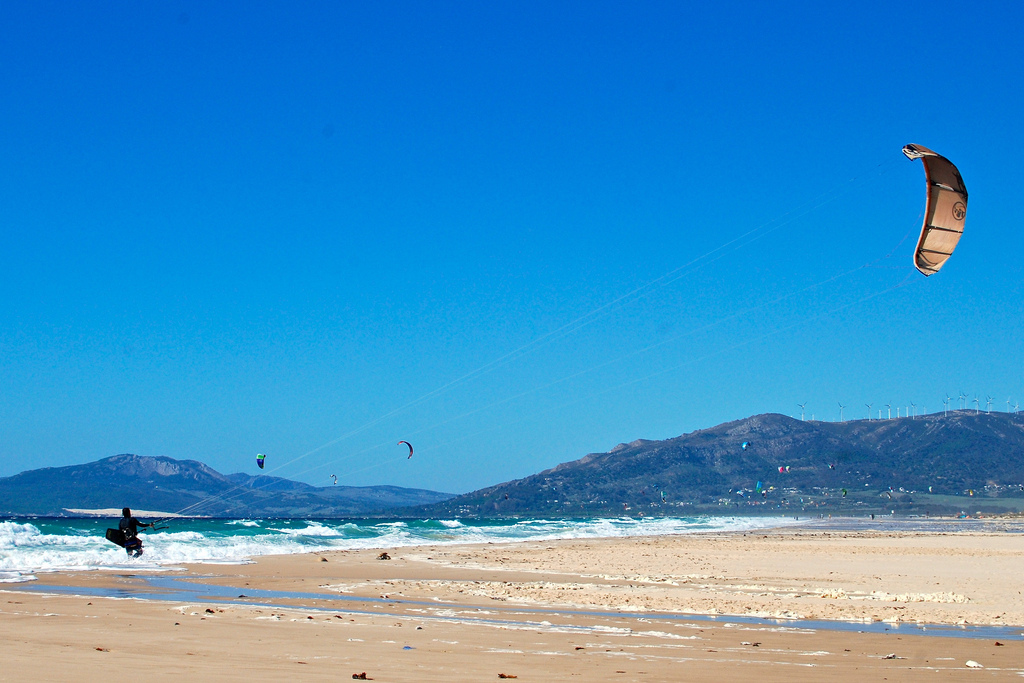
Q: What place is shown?
A: It is a beach.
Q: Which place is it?
A: It is a beach.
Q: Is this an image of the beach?
A: Yes, it is showing the beach.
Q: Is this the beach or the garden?
A: It is the beach.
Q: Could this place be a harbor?
A: No, it is a beach.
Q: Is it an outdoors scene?
A: Yes, it is outdoors.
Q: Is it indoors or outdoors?
A: It is outdoors.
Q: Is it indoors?
A: No, it is outdoors.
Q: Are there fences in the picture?
A: No, there are no fences.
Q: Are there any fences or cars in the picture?
A: No, there are no fences or cars.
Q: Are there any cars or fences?
A: No, there are no fences or cars.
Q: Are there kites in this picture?
A: Yes, there is a kite.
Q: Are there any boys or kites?
A: Yes, there is a kite.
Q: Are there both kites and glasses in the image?
A: No, there is a kite but no glasses.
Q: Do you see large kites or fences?
A: Yes, there is a large kite.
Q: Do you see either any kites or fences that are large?
A: Yes, the kite is large.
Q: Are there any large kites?
A: Yes, there is a large kite.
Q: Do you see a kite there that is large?
A: Yes, there is a kite that is large.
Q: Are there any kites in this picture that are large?
A: Yes, there is a kite that is large.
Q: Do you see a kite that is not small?
A: Yes, there is a large kite.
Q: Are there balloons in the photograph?
A: No, there are no balloons.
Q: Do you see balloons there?
A: No, there are no balloons.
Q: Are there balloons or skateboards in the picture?
A: No, there are no balloons or skateboards.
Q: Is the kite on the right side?
A: Yes, the kite is on the right of the image.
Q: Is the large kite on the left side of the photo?
A: No, the kite is on the right of the image.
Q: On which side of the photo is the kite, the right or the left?
A: The kite is on the right of the image.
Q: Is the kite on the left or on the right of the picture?
A: The kite is on the right of the image.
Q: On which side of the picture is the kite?
A: The kite is on the right of the image.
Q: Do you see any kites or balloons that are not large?
A: No, there is a kite but it is large.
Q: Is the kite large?
A: Yes, the kite is large.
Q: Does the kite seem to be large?
A: Yes, the kite is large.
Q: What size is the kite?
A: The kite is large.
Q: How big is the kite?
A: The kite is large.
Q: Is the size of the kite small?
A: No, the kite is large.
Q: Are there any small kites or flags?
A: No, there is a kite but it is large.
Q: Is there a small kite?
A: No, there is a kite but it is large.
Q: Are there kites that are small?
A: No, there is a kite but it is large.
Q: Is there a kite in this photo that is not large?
A: No, there is a kite but it is large.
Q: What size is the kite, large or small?
A: The kite is large.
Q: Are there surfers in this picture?
A: Yes, there is a surfer.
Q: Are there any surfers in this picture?
A: Yes, there is a surfer.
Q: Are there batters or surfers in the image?
A: Yes, there is a surfer.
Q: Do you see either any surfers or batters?
A: Yes, there is a surfer.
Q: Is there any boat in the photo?
A: No, there are no boats.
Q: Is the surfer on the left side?
A: Yes, the surfer is on the left of the image.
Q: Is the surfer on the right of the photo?
A: No, the surfer is on the left of the image.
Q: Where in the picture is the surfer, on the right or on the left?
A: The surfer is on the left of the image.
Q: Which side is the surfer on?
A: The surfer is on the left of the image.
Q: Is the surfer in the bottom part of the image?
A: Yes, the surfer is in the bottom of the image.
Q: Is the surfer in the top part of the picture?
A: No, the surfer is in the bottom of the image.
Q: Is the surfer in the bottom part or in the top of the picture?
A: The surfer is in the bottom of the image.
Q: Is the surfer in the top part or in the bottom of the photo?
A: The surfer is in the bottom of the image.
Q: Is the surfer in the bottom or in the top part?
A: The surfer is in the bottom of the image.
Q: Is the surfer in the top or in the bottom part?
A: The surfer is in the bottom of the image.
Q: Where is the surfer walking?
A: The surfer is walking in the ocean.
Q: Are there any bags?
A: No, there are no bags.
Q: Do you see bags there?
A: No, there are no bags.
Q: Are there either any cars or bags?
A: No, there are no bags or cars.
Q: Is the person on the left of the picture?
A: Yes, the person is on the left of the image.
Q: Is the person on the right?
A: No, the person is on the left of the image.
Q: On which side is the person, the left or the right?
A: The person is on the left of the image.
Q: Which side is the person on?
A: The person is on the left of the image.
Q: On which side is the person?
A: The person is on the left of the image.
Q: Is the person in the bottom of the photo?
A: Yes, the person is in the bottom of the image.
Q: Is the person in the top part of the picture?
A: No, the person is in the bottom of the image.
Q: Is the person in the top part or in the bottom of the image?
A: The person is in the bottom of the image.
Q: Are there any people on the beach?
A: Yes, there is a person on the beach.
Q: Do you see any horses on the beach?
A: No, there is a person on the beach.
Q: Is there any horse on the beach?
A: No, there is a person on the beach.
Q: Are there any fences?
A: No, there are no fences.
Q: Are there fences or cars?
A: No, there are no fences or cars.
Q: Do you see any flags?
A: No, there are no flags.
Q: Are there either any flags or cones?
A: No, there are no flags or cones.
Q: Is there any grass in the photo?
A: Yes, there is grass.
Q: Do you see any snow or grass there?
A: Yes, there is grass.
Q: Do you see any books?
A: No, there are no books.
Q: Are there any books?
A: No, there are no books.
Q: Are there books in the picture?
A: No, there are no books.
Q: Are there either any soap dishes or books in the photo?
A: No, there are no books or soap dishes.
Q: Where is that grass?
A: The grass is on the mountain.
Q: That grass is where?
A: The grass is on the mountain.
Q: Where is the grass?
A: The grass is on the mountain.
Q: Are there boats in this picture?
A: No, there are no boats.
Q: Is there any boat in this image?
A: No, there are no boats.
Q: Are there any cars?
A: No, there are no cars.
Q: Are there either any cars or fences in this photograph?
A: No, there are no cars or fences.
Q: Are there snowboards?
A: No, there are no snowboards.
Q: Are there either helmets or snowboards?
A: No, there are no snowboards or helmets.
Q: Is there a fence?
A: No, there are no fences.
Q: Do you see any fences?
A: No, there are no fences.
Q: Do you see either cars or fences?
A: No, there are no fences or cars.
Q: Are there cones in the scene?
A: No, there are no cones.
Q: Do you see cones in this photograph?
A: No, there are no cones.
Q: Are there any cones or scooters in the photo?
A: No, there are no cones or scooters.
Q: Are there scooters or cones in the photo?
A: No, there are no cones or scooters.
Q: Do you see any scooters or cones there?
A: No, there are no cones or scooters.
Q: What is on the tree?
A: The leaves are on the tree.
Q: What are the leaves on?
A: The leaves are on the tree.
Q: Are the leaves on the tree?
A: Yes, the leaves are on the tree.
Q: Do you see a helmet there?
A: No, there are no helmets.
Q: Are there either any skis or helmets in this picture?
A: No, there are no helmets or skis.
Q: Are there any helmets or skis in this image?
A: No, there are no helmets or skis.